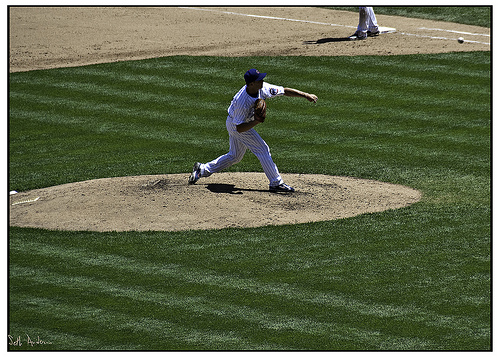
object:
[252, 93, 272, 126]
glove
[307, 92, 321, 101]
hand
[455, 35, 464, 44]
ball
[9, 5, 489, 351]
baseball field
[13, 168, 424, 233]
pitchers mound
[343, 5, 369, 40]
legs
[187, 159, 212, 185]
shoes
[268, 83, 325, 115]
left arm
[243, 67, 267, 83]
cap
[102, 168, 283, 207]
dirt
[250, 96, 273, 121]
mitt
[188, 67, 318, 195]
baseball player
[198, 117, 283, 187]
white sock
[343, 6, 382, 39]
player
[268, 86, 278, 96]
decal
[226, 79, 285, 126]
shirt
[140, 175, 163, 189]
rubber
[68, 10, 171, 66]
dirt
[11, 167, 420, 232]
dirt mound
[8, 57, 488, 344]
grass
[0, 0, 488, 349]
infield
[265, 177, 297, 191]
shoe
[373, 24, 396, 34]
base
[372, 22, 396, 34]
first base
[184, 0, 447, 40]
line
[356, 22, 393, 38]
home plate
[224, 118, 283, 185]
stripes